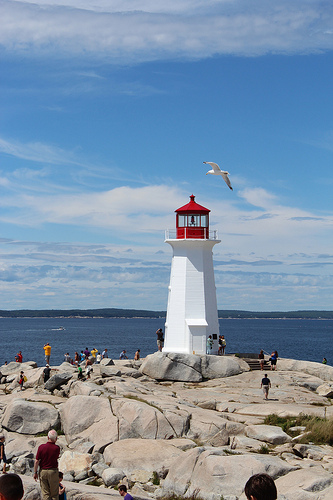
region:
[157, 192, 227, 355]
a red and white lighthouse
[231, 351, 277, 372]
stairs going up to a lighthouse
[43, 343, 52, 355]
a yellow shirt on a man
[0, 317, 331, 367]
water past a lighthouse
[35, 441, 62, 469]
a maroon shirt on a man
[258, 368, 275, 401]
a person walking toward a lighthouse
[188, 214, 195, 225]
the light in a lighthouse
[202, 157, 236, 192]
a white bird flying above a lighthouse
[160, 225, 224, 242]
white railing at the top of a lighthouse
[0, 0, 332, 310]
a beautiful blue cloudy sky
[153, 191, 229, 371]
A lighthouse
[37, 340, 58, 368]
Person taking a photograph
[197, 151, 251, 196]
A seagull in flight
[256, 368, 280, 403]
A man walking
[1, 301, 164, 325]
Treeline of a lake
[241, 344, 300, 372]
Two women by a stairway.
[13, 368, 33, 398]
People on a rock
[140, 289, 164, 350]
A man taking a photograph of the sky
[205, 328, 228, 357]
People reading a plaque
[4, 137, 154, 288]
Clouds in the sky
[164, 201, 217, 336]
this is a tower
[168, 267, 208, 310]
the wall is white in color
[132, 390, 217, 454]
these are the rocks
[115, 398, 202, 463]
the rocks are big in size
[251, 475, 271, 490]
this is the hair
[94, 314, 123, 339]
this is the sea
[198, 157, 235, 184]
this is a bird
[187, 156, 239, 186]
the bird is on air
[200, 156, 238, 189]
the bird is white in color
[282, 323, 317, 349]
the sea is calm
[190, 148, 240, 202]
bird in the sky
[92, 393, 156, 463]
patch of hard rocks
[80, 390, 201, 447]
set of uneven boulders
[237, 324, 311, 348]
beautiful area of water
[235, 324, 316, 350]
beautiful area of blue water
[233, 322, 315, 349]
blue area of water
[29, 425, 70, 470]
man wearing red shirt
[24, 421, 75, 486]
older man with red shirt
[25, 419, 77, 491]
mature man with red shirt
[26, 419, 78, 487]
mature older man with shirt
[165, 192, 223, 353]
Large tall red and white lighthouse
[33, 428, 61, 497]
Tall skinny old man with grey hair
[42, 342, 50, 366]
Fat man with yellow shirt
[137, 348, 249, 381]
Large heavy grey rock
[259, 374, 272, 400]
Man walking with black shirt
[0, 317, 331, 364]
Large open body of blue water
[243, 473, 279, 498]
Round dark bowl cut hair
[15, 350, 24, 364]
Small fat person wearing red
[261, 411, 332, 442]
Large tall tuft of grass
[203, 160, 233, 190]
Large white flying bird